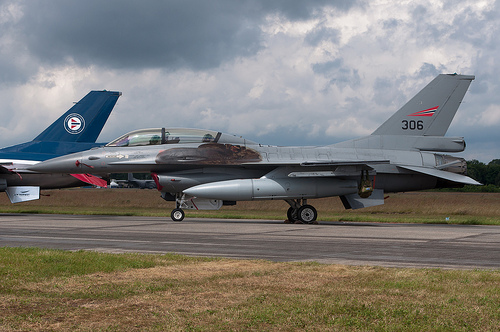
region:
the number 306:
[398, 119, 428, 133]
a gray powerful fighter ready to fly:
[39, 69, 483, 225]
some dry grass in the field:
[45, 253, 325, 323]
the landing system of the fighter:
[168, 196, 315, 221]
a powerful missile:
[180, 175, 355, 200]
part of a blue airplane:
[13, 83, 111, 150]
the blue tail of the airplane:
[35, 83, 117, 143]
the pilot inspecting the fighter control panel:
[140, 130, 163, 146]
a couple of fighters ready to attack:
[0, 81, 498, 241]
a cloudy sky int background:
[156, 52, 376, 128]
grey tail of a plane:
[377, 72, 474, 132]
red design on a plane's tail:
[405, 105, 435, 117]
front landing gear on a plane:
[169, 203, 185, 223]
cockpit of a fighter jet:
[101, 127, 221, 144]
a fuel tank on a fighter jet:
[180, 178, 358, 200]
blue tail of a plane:
[40, 88, 118, 142]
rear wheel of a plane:
[297, 203, 317, 223]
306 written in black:
[400, 118, 422, 131]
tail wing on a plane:
[3, 183, 38, 203]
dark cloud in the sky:
[0, 1, 331, 91]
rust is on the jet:
[161, 134, 259, 194]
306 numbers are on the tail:
[398, 112, 433, 136]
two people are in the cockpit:
[93, 117, 230, 170]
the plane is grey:
[64, 75, 476, 239]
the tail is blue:
[28, 98, 98, 160]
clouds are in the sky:
[31, 0, 329, 105]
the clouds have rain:
[13, 4, 320, 101]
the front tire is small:
[168, 201, 202, 228]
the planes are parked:
[31, 75, 475, 250]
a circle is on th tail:
[57, 113, 94, 143]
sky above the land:
[198, 12, 309, 96]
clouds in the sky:
[223, 35, 338, 102]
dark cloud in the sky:
[111, 25, 208, 72]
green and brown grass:
[64, 250, 141, 312]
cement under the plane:
[256, 224, 325, 259]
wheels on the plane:
[281, 197, 328, 229]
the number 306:
[396, 108, 433, 138]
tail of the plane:
[378, 63, 480, 168]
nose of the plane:
[16, 129, 114, 195]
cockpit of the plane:
[110, 120, 205, 157]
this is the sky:
[71, 12, 341, 68]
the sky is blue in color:
[468, 133, 494, 150]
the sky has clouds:
[113, 18, 373, 107]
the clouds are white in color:
[186, 66, 321, 124]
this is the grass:
[8, 250, 73, 272]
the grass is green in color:
[12, 248, 50, 275]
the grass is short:
[11, 250, 128, 293]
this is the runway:
[193, 219, 295, 255]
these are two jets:
[11, 68, 495, 223]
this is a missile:
[178, 175, 368, 195]